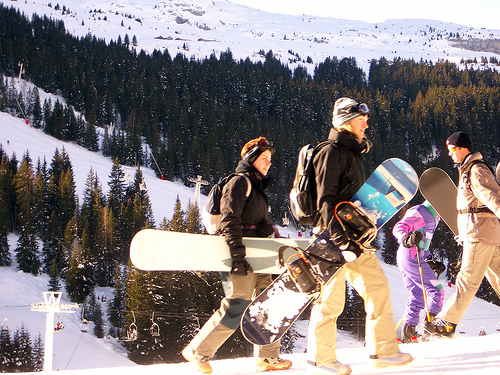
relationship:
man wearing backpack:
[422, 131, 499, 339] [293, 144, 321, 228]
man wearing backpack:
[288, 97, 412, 375] [293, 144, 321, 228]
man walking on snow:
[422, 131, 499, 339] [0, 113, 499, 371]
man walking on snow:
[288, 97, 412, 375] [0, 113, 499, 371]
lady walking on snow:
[181, 135, 293, 374] [0, 113, 499, 371]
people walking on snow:
[393, 190, 455, 343] [0, 113, 499, 371]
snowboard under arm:
[127, 227, 316, 275] [219, 177, 255, 277]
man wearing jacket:
[283, 92, 418, 372] [313, 125, 367, 232]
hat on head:
[328, 95, 368, 130] [331, 93, 373, 143]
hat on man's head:
[448, 127, 473, 147] [442, 117, 485, 169]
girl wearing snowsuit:
[387, 196, 454, 347] [391, 201, 445, 334]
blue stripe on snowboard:
[385, 158, 417, 193] [240, 157, 419, 347]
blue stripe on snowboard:
[355, 183, 395, 227] [240, 157, 419, 347]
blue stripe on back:
[385, 158, 419, 193] [243, 155, 423, 351]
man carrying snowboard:
[288, 97, 412, 375] [240, 157, 419, 347]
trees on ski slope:
[8, 141, 281, 351] [2, 106, 497, 373]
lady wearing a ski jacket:
[181, 135, 293, 374] [219, 176, 291, 277]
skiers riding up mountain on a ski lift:
[107, 306, 165, 354] [32, 287, 212, 374]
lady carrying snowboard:
[181, 135, 293, 374] [120, 225, 304, 277]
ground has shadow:
[0, 332, 499, 374] [349, 348, 499, 374]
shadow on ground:
[349, 348, 499, 374] [0, 332, 499, 374]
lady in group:
[181, 135, 293, 374] [180, 94, 484, 373]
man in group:
[288, 97, 412, 375] [180, 94, 484, 373]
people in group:
[392, 199, 458, 343] [180, 94, 484, 373]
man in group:
[422, 131, 499, 339] [180, 94, 484, 373]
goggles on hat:
[340, 97, 373, 116] [325, 101, 380, 144]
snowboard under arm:
[240, 157, 419, 347] [311, 141, 351, 244]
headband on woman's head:
[240, 138, 273, 160] [241, 137, 275, 177]